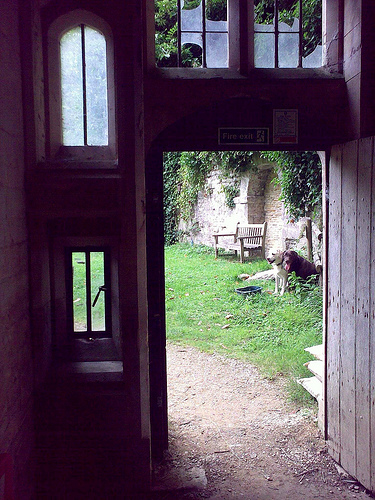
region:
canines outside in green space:
[257, 238, 311, 293]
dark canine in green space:
[284, 250, 320, 281]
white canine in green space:
[265, 245, 288, 291]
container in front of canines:
[236, 279, 263, 296]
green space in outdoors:
[173, 257, 301, 358]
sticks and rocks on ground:
[184, 415, 323, 486]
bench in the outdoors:
[210, 221, 274, 262]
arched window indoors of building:
[47, 6, 110, 148]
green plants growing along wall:
[163, 161, 317, 209]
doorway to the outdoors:
[169, 157, 323, 498]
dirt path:
[182, 380, 298, 482]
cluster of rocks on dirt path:
[271, 431, 328, 472]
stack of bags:
[299, 338, 323, 401]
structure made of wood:
[327, 206, 361, 469]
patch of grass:
[215, 295, 277, 345]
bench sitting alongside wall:
[216, 219, 261, 257]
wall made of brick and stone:
[194, 171, 278, 200]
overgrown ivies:
[166, 158, 307, 185]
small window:
[64, 242, 109, 345]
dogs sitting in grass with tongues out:
[261, 237, 314, 294]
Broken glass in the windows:
[144, 2, 327, 75]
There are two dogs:
[245, 246, 315, 297]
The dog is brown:
[283, 248, 315, 286]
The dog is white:
[255, 245, 289, 296]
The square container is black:
[234, 281, 262, 298]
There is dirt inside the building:
[134, 419, 367, 494]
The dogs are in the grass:
[262, 243, 318, 303]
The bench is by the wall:
[211, 221, 266, 262]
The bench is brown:
[209, 221, 266, 263]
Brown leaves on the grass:
[168, 274, 254, 343]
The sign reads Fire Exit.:
[221, 126, 270, 144]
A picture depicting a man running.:
[255, 128, 268, 145]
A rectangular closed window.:
[63, 242, 111, 346]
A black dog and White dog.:
[266, 241, 317, 294]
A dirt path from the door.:
[164, 352, 306, 494]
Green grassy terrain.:
[170, 251, 285, 374]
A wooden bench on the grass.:
[207, 221, 271, 262]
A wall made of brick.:
[187, 169, 285, 229]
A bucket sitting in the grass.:
[232, 279, 262, 300]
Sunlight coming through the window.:
[46, 21, 109, 152]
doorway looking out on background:
[143, 128, 341, 446]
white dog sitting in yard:
[261, 242, 286, 293]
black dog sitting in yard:
[277, 243, 311, 301]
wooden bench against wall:
[209, 217, 272, 266]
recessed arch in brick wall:
[243, 157, 289, 256]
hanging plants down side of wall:
[181, 150, 249, 221]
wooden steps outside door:
[295, 325, 328, 412]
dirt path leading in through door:
[169, 340, 301, 498]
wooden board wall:
[327, 155, 374, 463]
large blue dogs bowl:
[233, 276, 263, 306]